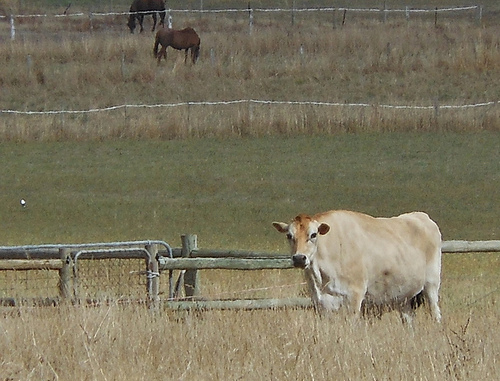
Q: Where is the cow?
A: In a field.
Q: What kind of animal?
A: Cow.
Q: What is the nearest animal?
A: Cow.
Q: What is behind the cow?
A: Fence.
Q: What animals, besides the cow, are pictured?
A: Horses.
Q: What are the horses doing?
A: Grazing.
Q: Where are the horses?
A: Pasture.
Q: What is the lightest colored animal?
A: Cow.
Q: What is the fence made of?
A: Wood.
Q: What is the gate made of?
A: Metal.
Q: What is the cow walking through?
A: Tall grass.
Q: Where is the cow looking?
A: Forward.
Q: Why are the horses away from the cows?
A: They are separated with wire fences.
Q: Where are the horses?
A: Between the fences on the background.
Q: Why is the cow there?
A: The cow feeds from the grass.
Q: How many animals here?
A: 3.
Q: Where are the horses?
A: In the next field.